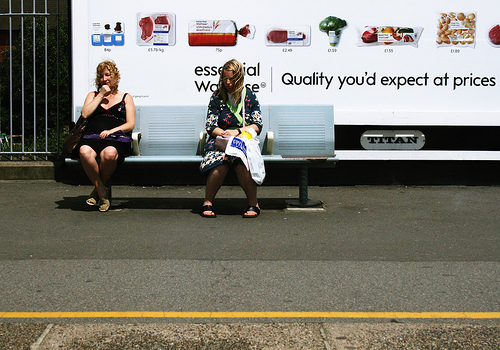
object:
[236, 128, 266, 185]
bags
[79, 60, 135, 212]
lady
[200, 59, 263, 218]
lady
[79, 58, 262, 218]
these ladies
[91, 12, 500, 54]
groceries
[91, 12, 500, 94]
billboard